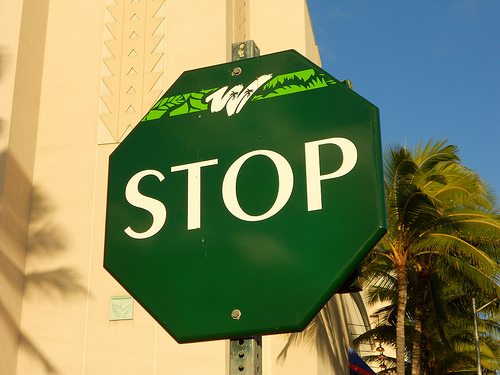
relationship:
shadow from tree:
[274, 280, 380, 374] [363, 135, 500, 374]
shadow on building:
[274, 280, 380, 374] [1, 0, 405, 374]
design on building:
[96, 1, 170, 145] [1, 0, 405, 374]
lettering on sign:
[122, 136, 358, 241] [102, 48, 388, 345]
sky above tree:
[307, 0, 498, 343] [363, 135, 500, 374]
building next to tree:
[1, 0, 405, 374] [363, 135, 500, 374]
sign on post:
[102, 48, 388, 345] [229, 334, 265, 374]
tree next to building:
[363, 135, 500, 374] [1, 0, 405, 374]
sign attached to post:
[102, 48, 388, 345] [229, 334, 265, 374]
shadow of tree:
[274, 280, 380, 374] [363, 135, 500, 374]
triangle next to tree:
[345, 345, 376, 373] [363, 135, 500, 374]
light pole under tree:
[470, 294, 497, 374] [363, 135, 500, 374]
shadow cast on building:
[274, 280, 380, 374] [1, 0, 405, 374]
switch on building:
[107, 293, 134, 322] [1, 0, 405, 374]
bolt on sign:
[229, 309, 243, 319] [102, 48, 388, 345]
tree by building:
[363, 135, 500, 374] [1, 0, 405, 374]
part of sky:
[366, 50, 417, 71] [307, 0, 498, 343]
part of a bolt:
[85, 212, 115, 320] [229, 309, 243, 319]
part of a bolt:
[88, 113, 146, 203] [229, 309, 243, 319]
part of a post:
[137, 254, 190, 333] [229, 334, 265, 374]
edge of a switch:
[356, 290, 466, 324] [107, 293, 134, 322]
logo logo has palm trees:
[141, 64, 337, 123] [359, 191, 448, 283]